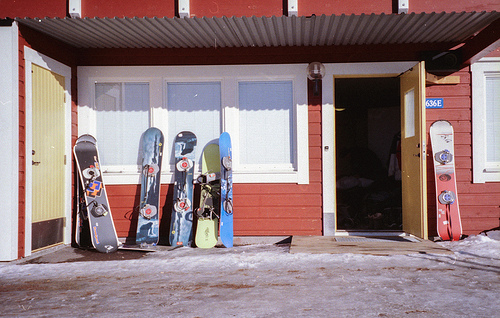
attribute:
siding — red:
[253, 191, 287, 209]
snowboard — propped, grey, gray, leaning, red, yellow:
[209, 135, 250, 209]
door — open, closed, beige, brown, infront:
[322, 59, 450, 203]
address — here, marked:
[426, 92, 451, 111]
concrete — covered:
[147, 290, 320, 309]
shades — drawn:
[240, 93, 286, 147]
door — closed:
[33, 66, 78, 230]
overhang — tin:
[171, 10, 337, 48]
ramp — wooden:
[299, 228, 378, 263]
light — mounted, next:
[303, 71, 342, 95]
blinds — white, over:
[238, 106, 319, 148]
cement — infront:
[203, 250, 379, 316]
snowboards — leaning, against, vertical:
[83, 108, 278, 230]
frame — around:
[314, 61, 347, 122]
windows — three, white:
[97, 72, 286, 153]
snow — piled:
[460, 225, 497, 255]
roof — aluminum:
[97, 12, 168, 44]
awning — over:
[131, 27, 379, 53]